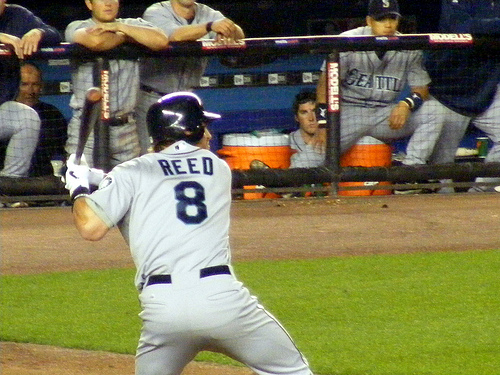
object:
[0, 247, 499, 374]
grass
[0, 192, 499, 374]
field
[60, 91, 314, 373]
player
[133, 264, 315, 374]
pants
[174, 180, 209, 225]
number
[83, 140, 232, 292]
jersey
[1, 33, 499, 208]
fence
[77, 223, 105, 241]
elbow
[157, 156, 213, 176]
writting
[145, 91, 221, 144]
helmet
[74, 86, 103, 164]
bat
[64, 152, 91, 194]
hands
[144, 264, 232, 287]
belt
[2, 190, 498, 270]
strip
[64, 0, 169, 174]
players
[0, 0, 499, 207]
dugout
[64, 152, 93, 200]
gloves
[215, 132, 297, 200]
cooler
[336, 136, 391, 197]
cooler